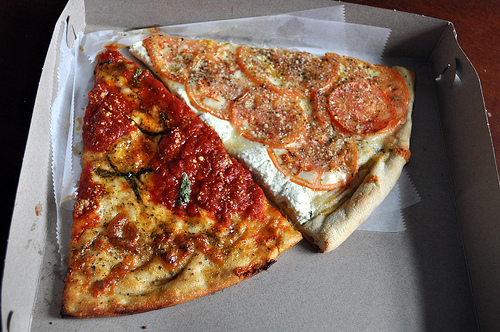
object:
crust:
[325, 207, 357, 242]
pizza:
[125, 33, 413, 247]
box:
[2, 0, 499, 329]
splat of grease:
[25, 221, 64, 307]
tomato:
[329, 80, 395, 143]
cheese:
[65, 50, 282, 293]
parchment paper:
[51, 5, 422, 278]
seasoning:
[149, 37, 379, 169]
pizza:
[62, 49, 305, 318]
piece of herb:
[176, 170, 193, 207]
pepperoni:
[230, 89, 303, 143]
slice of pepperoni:
[141, 28, 203, 86]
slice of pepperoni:
[182, 42, 249, 121]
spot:
[98, 59, 114, 68]